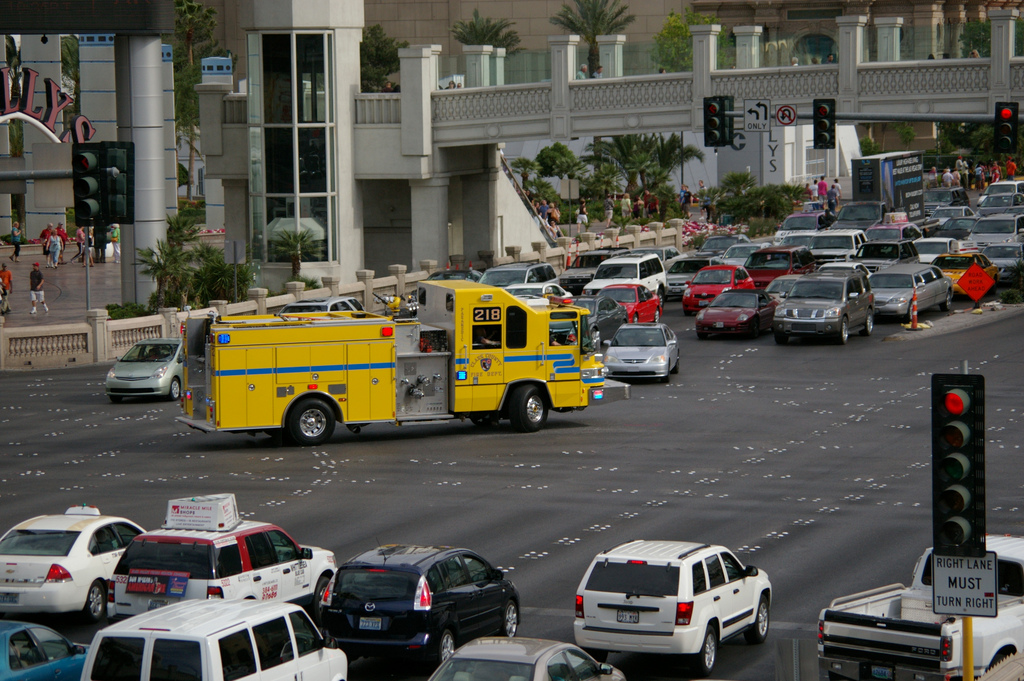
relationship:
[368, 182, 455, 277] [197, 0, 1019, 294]
wall on building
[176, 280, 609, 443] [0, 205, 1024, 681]
fire truck in road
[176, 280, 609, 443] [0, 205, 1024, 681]
fire truck on road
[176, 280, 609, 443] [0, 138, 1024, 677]
fire truck on road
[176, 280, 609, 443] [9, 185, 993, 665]
fire truck on street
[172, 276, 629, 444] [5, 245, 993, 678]
fire truck on road